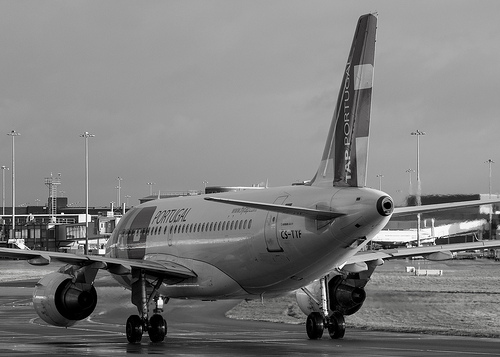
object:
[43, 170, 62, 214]
tower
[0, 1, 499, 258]
background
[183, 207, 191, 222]
letter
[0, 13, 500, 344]
airplane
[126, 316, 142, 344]
wheel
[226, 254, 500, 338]
grass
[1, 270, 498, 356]
tarmac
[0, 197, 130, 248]
building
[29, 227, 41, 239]
window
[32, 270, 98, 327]
engine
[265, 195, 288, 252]
door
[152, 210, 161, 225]
letter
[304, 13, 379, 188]
tail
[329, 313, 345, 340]
wheel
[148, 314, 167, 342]
wheel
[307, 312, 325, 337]
wheel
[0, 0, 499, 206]
sky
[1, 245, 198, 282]
wing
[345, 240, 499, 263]
wing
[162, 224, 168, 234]
window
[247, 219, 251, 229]
window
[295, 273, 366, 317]
engine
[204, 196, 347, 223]
wing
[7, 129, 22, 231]
lightpole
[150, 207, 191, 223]
word